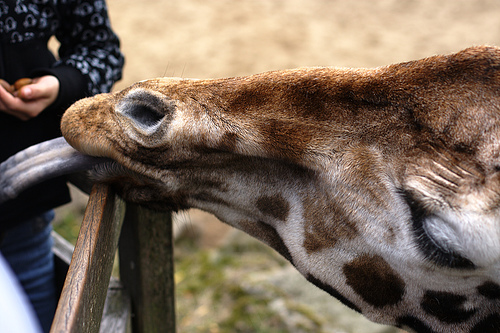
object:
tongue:
[1, 143, 119, 215]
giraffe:
[57, 43, 498, 333]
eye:
[394, 185, 478, 272]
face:
[59, 44, 499, 333]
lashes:
[393, 184, 476, 271]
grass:
[57, 200, 407, 331]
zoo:
[0, 0, 498, 330]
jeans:
[3, 210, 57, 331]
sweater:
[2, 1, 125, 213]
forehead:
[164, 47, 499, 191]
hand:
[0, 75, 59, 122]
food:
[9, 77, 36, 95]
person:
[2, 1, 124, 333]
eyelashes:
[392, 186, 475, 273]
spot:
[298, 174, 364, 254]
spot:
[341, 250, 408, 310]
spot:
[251, 189, 292, 222]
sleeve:
[42, 0, 131, 112]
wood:
[52, 180, 139, 327]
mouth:
[49, 96, 161, 187]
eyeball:
[394, 187, 477, 271]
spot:
[417, 283, 480, 326]